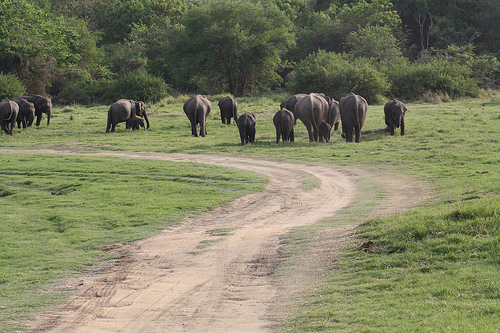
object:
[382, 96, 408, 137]
elephant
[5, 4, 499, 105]
trees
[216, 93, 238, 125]
elephant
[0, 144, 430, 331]
path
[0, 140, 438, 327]
sandy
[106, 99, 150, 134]
elephant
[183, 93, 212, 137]
elephant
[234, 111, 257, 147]
elephant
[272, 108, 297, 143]
elephant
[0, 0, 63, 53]
leaves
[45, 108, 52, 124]
trunk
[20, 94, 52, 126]
elephant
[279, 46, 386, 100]
heavy bush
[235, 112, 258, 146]
elephants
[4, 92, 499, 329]
field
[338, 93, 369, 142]
elephant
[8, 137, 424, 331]
track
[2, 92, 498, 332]
ground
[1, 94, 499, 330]
grass